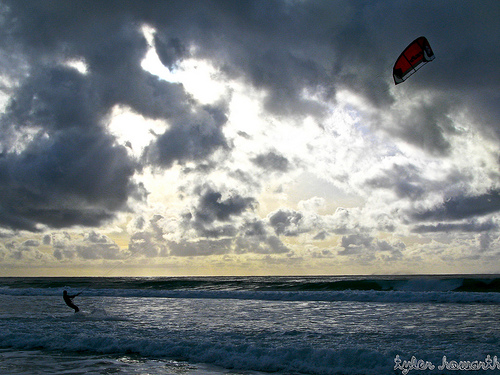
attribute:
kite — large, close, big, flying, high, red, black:
[367, 32, 453, 96]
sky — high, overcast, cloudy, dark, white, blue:
[70, 17, 343, 222]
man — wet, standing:
[49, 278, 90, 320]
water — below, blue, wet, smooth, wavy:
[181, 270, 346, 351]